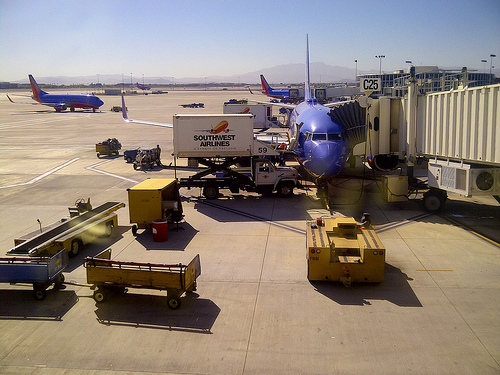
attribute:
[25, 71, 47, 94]
fin — red, blue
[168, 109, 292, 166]
truck — white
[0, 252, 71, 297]
cart — small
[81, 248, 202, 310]
cart — small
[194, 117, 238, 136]
plane — red, orange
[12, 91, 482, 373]
airport — large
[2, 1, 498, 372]
airport — large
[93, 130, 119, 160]
cart — small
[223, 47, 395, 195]
plane — large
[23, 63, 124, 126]
plane — blue 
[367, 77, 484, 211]
walkway — metal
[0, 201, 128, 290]
cart — small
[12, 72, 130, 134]
airplane — blue, red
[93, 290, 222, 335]
shadow — dark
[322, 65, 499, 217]
bridge — large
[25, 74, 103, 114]
plane — blue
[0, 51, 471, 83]
hills — distant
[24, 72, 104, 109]
planes — blue, red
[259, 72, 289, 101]
planes — blue, red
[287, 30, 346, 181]
planes — blue, red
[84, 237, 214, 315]
trolley — empty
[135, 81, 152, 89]
airplane — blue, red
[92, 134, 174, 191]
carts — rolling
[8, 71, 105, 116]
airplane — blue, red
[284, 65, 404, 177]
planes — stationary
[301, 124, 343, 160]
cockpit — large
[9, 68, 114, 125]
airplane — blue 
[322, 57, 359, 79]
mountains — distant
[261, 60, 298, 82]
mountains — distant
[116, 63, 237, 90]
mountains — distant